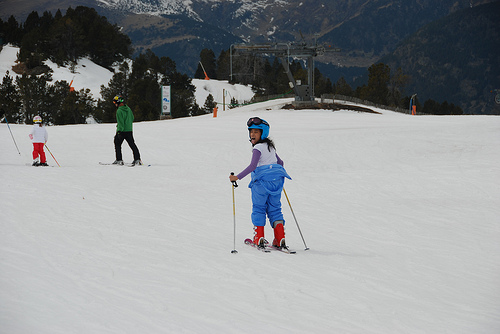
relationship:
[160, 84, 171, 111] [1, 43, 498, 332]
sign in snow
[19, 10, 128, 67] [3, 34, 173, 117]
trees on hill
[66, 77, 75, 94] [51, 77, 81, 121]
flag marking ski slope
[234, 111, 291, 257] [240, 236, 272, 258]
female wearing ski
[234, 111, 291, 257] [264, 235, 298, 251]
female wearing ski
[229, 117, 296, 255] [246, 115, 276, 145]
female wearing head gear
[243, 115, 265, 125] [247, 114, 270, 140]
goggles on head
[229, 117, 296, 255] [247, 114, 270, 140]
female has head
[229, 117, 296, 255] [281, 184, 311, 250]
female holding pole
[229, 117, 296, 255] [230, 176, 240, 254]
female holding pole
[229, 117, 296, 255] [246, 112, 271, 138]
female wearing hat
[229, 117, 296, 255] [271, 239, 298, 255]
female wearing ski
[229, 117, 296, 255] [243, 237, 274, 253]
female wearing ski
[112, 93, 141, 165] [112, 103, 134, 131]
guy wearing green jacket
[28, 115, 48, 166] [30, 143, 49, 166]
kid wearing red pants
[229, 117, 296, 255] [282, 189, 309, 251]
female holding snow stick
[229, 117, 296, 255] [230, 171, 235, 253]
female holding snow stick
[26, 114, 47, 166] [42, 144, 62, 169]
kid holding snow stick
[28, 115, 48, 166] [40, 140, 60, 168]
kid holding stick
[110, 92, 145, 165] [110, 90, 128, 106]
guy wearing hat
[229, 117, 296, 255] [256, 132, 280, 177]
female wearing vest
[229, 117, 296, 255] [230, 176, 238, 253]
female holding pole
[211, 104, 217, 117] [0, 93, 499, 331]
pole in ground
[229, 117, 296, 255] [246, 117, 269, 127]
female with goggles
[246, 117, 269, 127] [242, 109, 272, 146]
goggles on head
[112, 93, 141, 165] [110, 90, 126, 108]
guy with helmet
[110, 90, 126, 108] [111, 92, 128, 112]
helmet on head